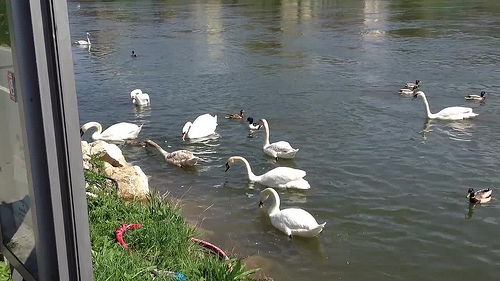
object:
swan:
[257, 186, 329, 238]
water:
[68, 0, 499, 280]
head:
[464, 188, 476, 199]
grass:
[84, 158, 265, 281]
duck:
[464, 187, 493, 204]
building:
[1, 0, 96, 281]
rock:
[100, 162, 151, 199]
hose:
[114, 222, 237, 269]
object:
[172, 270, 186, 280]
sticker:
[7, 71, 19, 103]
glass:
[2, 0, 56, 280]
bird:
[221, 156, 312, 189]